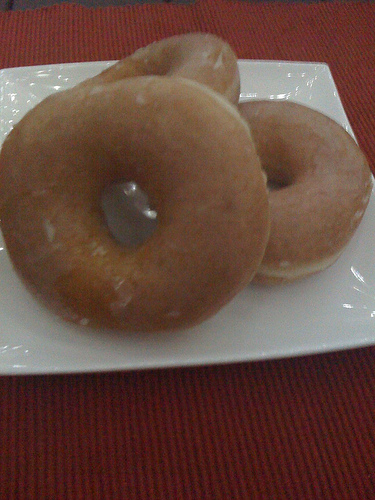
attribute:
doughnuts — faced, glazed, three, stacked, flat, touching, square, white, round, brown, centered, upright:
[9, 44, 374, 336]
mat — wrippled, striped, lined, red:
[19, 9, 374, 59]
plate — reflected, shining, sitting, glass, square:
[9, 55, 374, 393]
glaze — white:
[38, 194, 103, 297]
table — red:
[5, 15, 368, 229]